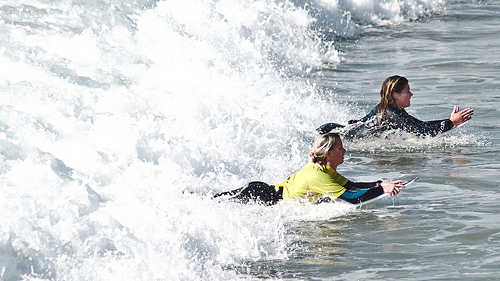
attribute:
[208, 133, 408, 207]
woman — white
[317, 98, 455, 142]
wet suit — black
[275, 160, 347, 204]
t-shirt — yellow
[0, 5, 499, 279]
water — splashing, rippled, blue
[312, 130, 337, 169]
hair — blonde, wet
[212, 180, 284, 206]
pants — black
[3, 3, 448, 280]
wave — small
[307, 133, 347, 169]
head — blonde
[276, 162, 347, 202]
shirt — yellow